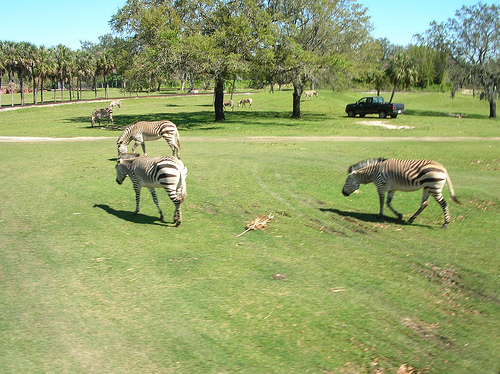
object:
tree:
[2, 39, 17, 107]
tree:
[226, 40, 240, 104]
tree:
[117, 45, 128, 97]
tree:
[130, 44, 140, 100]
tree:
[72, 50, 77, 99]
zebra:
[116, 119, 182, 163]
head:
[341, 168, 361, 197]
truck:
[342, 95, 407, 119]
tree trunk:
[291, 77, 302, 119]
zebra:
[336, 150, 463, 230]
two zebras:
[109, 119, 195, 228]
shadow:
[319, 204, 434, 230]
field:
[0, 69, 500, 374]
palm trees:
[83, 40, 101, 99]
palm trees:
[4, 43, 20, 106]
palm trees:
[361, 54, 390, 97]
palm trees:
[385, 50, 419, 104]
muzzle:
[341, 190, 349, 197]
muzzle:
[115, 177, 123, 185]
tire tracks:
[239, 154, 497, 371]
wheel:
[378, 111, 387, 119]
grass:
[2, 81, 499, 370]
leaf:
[234, 209, 275, 237]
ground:
[0, 89, 498, 371]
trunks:
[210, 77, 228, 122]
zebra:
[88, 106, 115, 129]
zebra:
[108, 98, 122, 109]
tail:
[442, 165, 463, 206]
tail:
[179, 169, 189, 199]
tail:
[175, 125, 183, 149]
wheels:
[347, 110, 355, 118]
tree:
[252, 5, 347, 119]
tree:
[162, 5, 268, 125]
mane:
[348, 155, 388, 173]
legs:
[375, 185, 387, 219]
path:
[185, 130, 499, 145]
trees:
[428, 4, 500, 120]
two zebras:
[221, 96, 254, 112]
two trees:
[108, 0, 366, 126]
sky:
[0, 0, 500, 70]